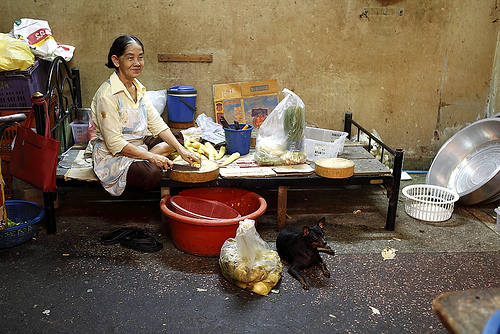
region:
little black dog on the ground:
[271, 220, 351, 293]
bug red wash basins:
[156, 185, 280, 268]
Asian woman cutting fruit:
[87, 31, 200, 188]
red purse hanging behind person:
[10, 92, 67, 197]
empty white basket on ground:
[400, 178, 455, 223]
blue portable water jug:
[155, 79, 210, 124]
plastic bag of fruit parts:
[248, 91, 306, 168]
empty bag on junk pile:
[10, 13, 76, 65]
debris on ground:
[338, 235, 411, 305]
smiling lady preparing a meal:
[83, 27, 230, 197]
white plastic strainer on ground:
[403, 182, 458, 225]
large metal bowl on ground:
[437, 112, 494, 206]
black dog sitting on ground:
[278, 207, 335, 287]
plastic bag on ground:
[224, 232, 273, 300]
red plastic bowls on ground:
[164, 192, 239, 241]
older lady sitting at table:
[97, 31, 178, 208]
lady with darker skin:
[97, 26, 156, 85]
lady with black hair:
[106, 30, 146, 84]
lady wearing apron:
[103, 35, 185, 199]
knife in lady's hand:
[133, 144, 218, 177]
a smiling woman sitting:
[83, 33, 203, 195]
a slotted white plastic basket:
[400, 181, 453, 218]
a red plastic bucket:
[168, 192, 238, 222]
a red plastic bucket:
[157, 185, 266, 255]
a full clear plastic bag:
[217, 218, 279, 298]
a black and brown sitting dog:
[275, 220, 332, 286]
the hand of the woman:
[152, 150, 170, 169]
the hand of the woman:
[179, 148, 201, 164]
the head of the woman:
[105, 33, 145, 74]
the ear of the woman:
[110, 52, 120, 67]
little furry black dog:
[276, 214, 342, 296]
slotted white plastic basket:
[392, 176, 462, 228]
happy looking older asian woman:
[80, 24, 197, 239]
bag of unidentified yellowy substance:
[205, 214, 286, 299]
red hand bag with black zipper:
[8, 89, 65, 191]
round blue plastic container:
[164, 76, 199, 127]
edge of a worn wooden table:
[410, 271, 499, 330]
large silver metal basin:
[422, 108, 498, 204]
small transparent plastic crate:
[300, 117, 352, 164]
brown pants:
[119, 123, 185, 193]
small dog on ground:
[261, 216, 343, 306]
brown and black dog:
[268, 217, 360, 297]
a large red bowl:
[148, 194, 262, 263]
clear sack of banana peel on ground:
[203, 202, 285, 327]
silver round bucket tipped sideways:
[428, 97, 488, 227]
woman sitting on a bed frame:
[6, 47, 401, 202]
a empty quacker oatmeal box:
[205, 69, 285, 163]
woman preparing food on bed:
[55, 56, 250, 236]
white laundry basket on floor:
[398, 171, 469, 230]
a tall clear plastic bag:
[228, 81, 323, 183]